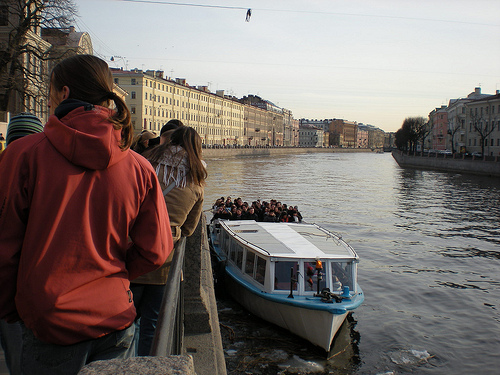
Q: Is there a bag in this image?
A: No, there are no bags.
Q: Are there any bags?
A: No, there are no bags.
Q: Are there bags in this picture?
A: No, there are no bags.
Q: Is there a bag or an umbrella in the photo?
A: No, there are no bags or umbrellas.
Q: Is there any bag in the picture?
A: No, there are no bags.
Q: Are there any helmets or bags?
A: No, there are no bags or helmets.